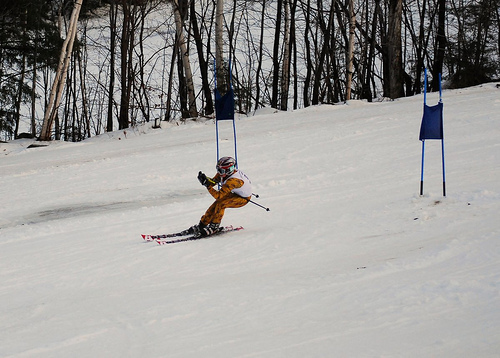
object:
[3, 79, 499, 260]
slope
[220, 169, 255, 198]
vest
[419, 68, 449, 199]
flag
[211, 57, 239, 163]
flag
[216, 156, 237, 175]
helmet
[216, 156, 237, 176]
head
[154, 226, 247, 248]
skis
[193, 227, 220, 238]
feet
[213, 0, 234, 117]
trees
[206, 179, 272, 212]
ski poles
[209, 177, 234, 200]
arms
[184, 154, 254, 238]
kid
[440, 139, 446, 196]
poles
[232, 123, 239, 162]
poles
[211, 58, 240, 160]
left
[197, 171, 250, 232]
snow suit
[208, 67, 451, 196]
gate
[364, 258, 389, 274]
snow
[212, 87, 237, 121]
sign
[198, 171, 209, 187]
gloves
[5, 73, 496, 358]
landscape